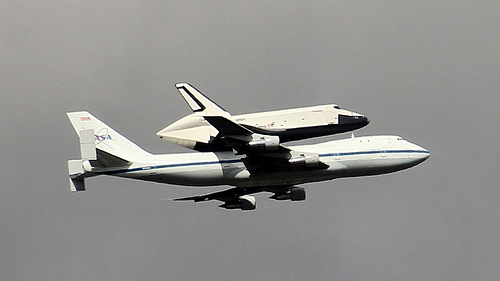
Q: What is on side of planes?
A: No windows.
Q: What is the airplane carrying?
A: Space shuttle.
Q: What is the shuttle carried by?
A: A plane.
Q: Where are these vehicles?
A: In the sky.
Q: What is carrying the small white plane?
A: The large white plane.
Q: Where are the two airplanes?
A: In the sky.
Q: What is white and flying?
A: The planes.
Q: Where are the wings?
A: On the side of the plane.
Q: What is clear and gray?
A: The sky.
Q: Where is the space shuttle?
A: On top of the plane.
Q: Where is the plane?
A: Beneath the space shuttle.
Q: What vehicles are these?
A: Plane and space shuttle.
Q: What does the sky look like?
A: Grey.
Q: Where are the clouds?
A: Behind the aircrafts.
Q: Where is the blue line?
A: On the large plane.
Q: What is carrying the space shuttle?
A: The plane.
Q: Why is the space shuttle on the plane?
A: It is being transported.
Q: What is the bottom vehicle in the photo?
A: Plane.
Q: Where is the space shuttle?
A: On the plane.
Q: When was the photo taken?
A: Daytime.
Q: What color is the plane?
A: White.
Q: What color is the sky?
A: Gray.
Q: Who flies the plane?
A: Pilot.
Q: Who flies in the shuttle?
A: Astronaut.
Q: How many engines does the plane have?
A: Four.